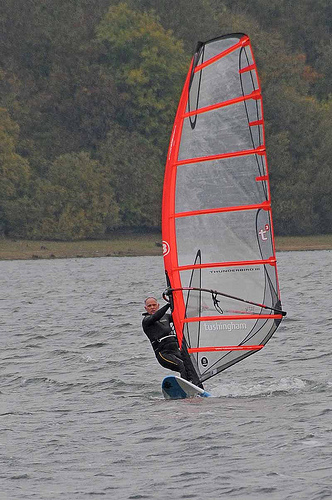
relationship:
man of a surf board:
[140, 294, 203, 389] [158, 374, 212, 397]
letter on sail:
[258, 228, 267, 239] [160, 31, 287, 384]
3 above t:
[264, 223, 270, 229] [256, 229, 271, 246]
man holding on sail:
[140, 294, 203, 389] [143, 25, 328, 300]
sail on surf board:
[160, 31, 287, 384] [160, 376, 211, 400]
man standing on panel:
[140, 294, 203, 389] [161, 373, 210, 398]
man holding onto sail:
[140, 294, 203, 389] [149, 28, 288, 398]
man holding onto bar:
[140, 294, 203, 389] [162, 286, 286, 319]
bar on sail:
[162, 286, 286, 319] [149, 28, 288, 398]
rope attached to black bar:
[208, 289, 222, 313] [162, 287, 286, 316]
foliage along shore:
[1, 1, 330, 240] [2, 237, 331, 258]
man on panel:
[140, 294, 203, 389] [161, 373, 210, 398]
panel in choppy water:
[161, 373, 210, 398] [0, 246, 331, 498]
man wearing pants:
[130, 291, 201, 408] [153, 347, 203, 382]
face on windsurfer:
[143, 295, 157, 317] [125, 33, 288, 401]